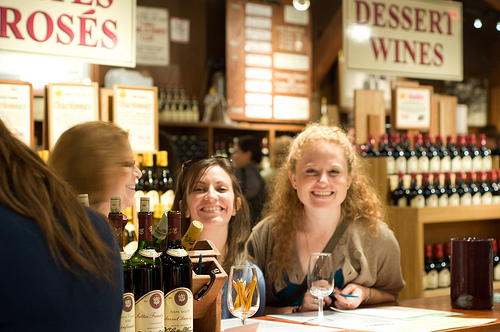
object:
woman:
[281, 123, 374, 301]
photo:
[0, 0, 481, 313]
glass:
[301, 252, 338, 324]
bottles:
[382, 133, 406, 173]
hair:
[269, 160, 297, 279]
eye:
[329, 166, 343, 174]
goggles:
[179, 153, 233, 166]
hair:
[0, 141, 117, 278]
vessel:
[448, 232, 496, 310]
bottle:
[161, 201, 192, 332]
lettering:
[0, 5, 116, 48]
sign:
[343, 0, 463, 82]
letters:
[365, 35, 396, 63]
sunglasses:
[176, 154, 233, 171]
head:
[178, 163, 242, 225]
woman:
[48, 119, 144, 227]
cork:
[139, 196, 153, 210]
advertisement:
[352, 0, 455, 70]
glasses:
[224, 260, 262, 332]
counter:
[255, 297, 500, 331]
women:
[146, 153, 261, 323]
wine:
[161, 207, 193, 329]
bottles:
[135, 193, 168, 332]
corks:
[107, 195, 121, 213]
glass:
[227, 262, 260, 331]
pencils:
[243, 275, 255, 313]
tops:
[413, 133, 425, 144]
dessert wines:
[353, 0, 456, 67]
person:
[229, 138, 270, 240]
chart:
[230, 3, 311, 122]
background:
[112, 1, 453, 99]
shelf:
[161, 114, 324, 132]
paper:
[322, 310, 459, 329]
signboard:
[223, 0, 321, 123]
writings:
[0, 7, 121, 52]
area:
[296, 7, 500, 119]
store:
[55, 38, 500, 248]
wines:
[473, 167, 499, 205]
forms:
[287, 304, 495, 331]